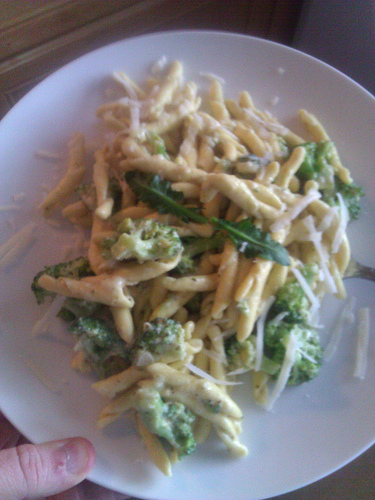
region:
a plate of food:
[35, 38, 343, 498]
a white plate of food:
[21, 9, 372, 482]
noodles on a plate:
[32, 32, 318, 498]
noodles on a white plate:
[4, 13, 342, 497]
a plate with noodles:
[24, 17, 374, 476]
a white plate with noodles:
[9, 25, 351, 482]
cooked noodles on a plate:
[22, 20, 344, 498]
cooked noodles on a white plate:
[9, 29, 363, 497]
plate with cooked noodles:
[9, 4, 345, 499]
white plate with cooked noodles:
[10, 21, 372, 484]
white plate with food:
[3, 20, 363, 487]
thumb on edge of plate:
[0, 430, 93, 490]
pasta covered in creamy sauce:
[45, 87, 345, 433]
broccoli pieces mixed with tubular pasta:
[78, 130, 326, 439]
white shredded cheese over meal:
[166, 225, 327, 401]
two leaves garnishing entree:
[122, 165, 289, 270]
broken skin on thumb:
[47, 430, 68, 490]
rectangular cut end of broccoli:
[109, 225, 129, 266]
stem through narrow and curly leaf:
[210, 211, 292, 267]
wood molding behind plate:
[3, 4, 211, 114]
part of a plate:
[64, 64, 95, 99]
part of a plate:
[276, 440, 299, 480]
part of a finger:
[30, 455, 63, 481]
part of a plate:
[254, 413, 274, 462]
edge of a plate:
[306, 461, 330, 492]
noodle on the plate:
[50, 280, 118, 306]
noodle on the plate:
[211, 418, 241, 448]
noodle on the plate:
[137, 440, 183, 470]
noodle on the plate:
[230, 273, 260, 329]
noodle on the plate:
[218, 253, 236, 313]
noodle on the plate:
[224, 193, 277, 228]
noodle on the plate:
[200, 181, 257, 215]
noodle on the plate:
[222, 179, 262, 206]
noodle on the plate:
[202, 126, 233, 157]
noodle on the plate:
[309, 244, 327, 286]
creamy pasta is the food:
[80, 121, 345, 452]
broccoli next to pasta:
[138, 392, 191, 457]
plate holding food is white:
[244, 355, 367, 498]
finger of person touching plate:
[4, 441, 102, 498]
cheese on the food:
[305, 196, 344, 295]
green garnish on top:
[142, 173, 290, 255]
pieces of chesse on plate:
[253, 52, 298, 121]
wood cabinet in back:
[1, 1, 65, 79]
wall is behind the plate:
[307, 3, 369, 78]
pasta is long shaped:
[215, 235, 233, 318]